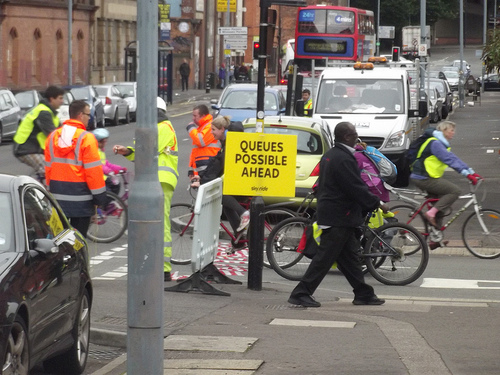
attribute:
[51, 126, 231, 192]
coats — orange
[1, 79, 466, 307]
city street — busy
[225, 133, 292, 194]
sign — yellow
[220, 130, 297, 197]
yellow sign — big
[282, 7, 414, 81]
bus — bred, blue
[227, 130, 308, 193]
sign — big, yellow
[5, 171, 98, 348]
car — black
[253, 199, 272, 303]
pole — black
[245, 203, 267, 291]
pole — black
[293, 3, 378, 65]
bus — double decker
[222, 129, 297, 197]
sign — big, yellow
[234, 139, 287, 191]
words — black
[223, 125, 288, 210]
sign — yellow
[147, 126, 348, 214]
sign — big, yellow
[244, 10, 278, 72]
pole — black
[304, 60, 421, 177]
truck — white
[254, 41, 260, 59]
light — red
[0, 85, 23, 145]
car — parked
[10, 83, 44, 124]
car — parked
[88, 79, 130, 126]
car — parked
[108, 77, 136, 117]
car — parked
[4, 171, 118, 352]
car — parked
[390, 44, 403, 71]
light — red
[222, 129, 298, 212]
warning sign — big, yellow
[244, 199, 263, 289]
pole — black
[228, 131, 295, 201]
sign — yellow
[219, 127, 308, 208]
warning sign — big, yellow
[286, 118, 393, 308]
man — walking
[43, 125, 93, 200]
coat — orange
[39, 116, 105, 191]
coat — orange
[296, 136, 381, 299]
suit — black